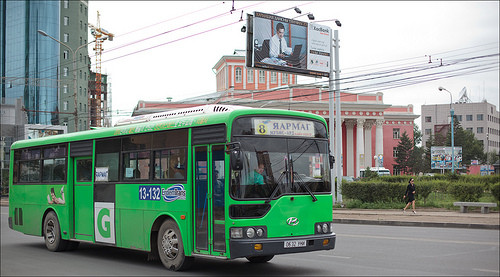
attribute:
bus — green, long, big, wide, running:
[4, 106, 344, 266]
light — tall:
[34, 25, 82, 131]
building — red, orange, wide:
[126, 46, 424, 185]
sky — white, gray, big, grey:
[82, 2, 496, 108]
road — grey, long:
[1, 197, 499, 275]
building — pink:
[135, 44, 424, 196]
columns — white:
[322, 87, 385, 185]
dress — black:
[406, 182, 415, 203]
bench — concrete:
[453, 194, 498, 215]